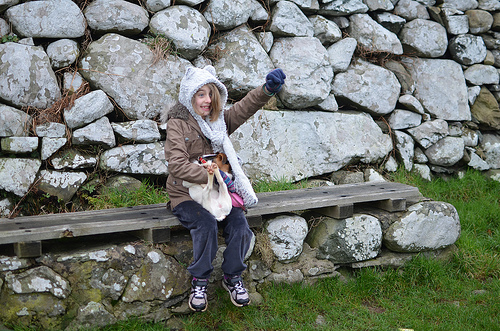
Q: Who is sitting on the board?
A: Girl with raised fist.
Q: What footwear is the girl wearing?
A: Sneakers.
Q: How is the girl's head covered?
A: Hoodie.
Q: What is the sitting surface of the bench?
A: Wood.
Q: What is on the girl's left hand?
A: Blue glove.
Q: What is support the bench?
A: Four by fours and rocks.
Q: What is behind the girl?
A: Rock wall.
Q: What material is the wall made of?
A: Stone.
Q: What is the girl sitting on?
A: Bench.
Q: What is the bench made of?
A: Wood on top of rocks.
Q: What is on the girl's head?
A: Crocheted hood.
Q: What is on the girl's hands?
A: Blue gloves.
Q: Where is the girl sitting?
A: On a bench in front of rocks.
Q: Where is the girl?
A: On bench.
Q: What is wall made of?
A: Rock.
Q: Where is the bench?
A: On wall.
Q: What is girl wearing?
A: Brown coat.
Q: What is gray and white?
A: Rocks.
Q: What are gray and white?
A: Rocks.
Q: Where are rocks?
A: Under bench.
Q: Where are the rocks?
A: In wall.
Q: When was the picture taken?
A: Daytime.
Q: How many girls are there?
A: One.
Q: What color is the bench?
A: Brown.